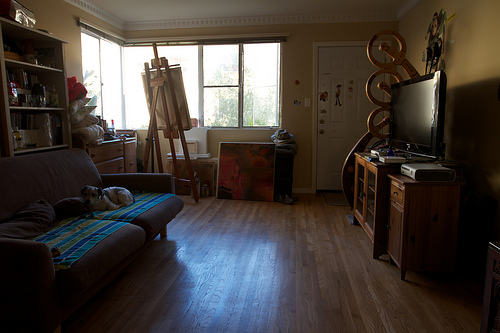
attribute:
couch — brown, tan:
[0, 146, 188, 331]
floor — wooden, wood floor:
[47, 193, 500, 333]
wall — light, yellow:
[124, 21, 400, 193]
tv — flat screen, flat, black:
[380, 68, 448, 160]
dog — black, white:
[80, 183, 135, 214]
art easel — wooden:
[136, 42, 203, 206]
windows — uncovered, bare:
[78, 22, 286, 129]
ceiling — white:
[87, 0, 400, 22]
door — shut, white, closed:
[312, 39, 398, 193]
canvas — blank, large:
[138, 66, 195, 130]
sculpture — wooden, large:
[341, 30, 425, 211]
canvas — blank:
[180, 125, 208, 155]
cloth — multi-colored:
[30, 187, 173, 271]